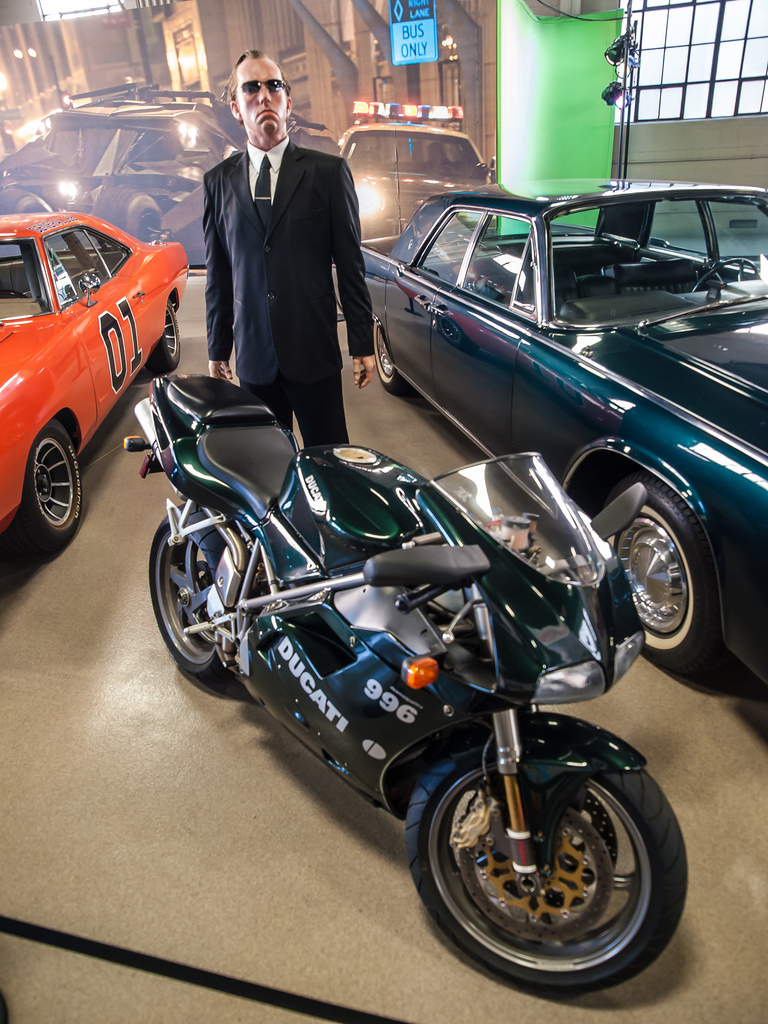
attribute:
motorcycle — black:
[117, 367, 699, 1000]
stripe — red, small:
[515, 835, 530, 869]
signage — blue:
[389, 0, 437, 68]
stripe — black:
[2, 913, 398, 1020]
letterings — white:
[64, 444, 83, 520]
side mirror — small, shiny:
[82, 269, 102, 306]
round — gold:
[335, 444, 381, 466]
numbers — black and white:
[97, 299, 144, 384]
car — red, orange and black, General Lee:
[0, 206, 194, 541]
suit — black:
[200, 144, 371, 447]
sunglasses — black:
[242, 79, 286, 92]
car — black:
[354, 181, 765, 685]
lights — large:
[600, 29, 641, 108]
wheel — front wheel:
[413, 719, 686, 995]